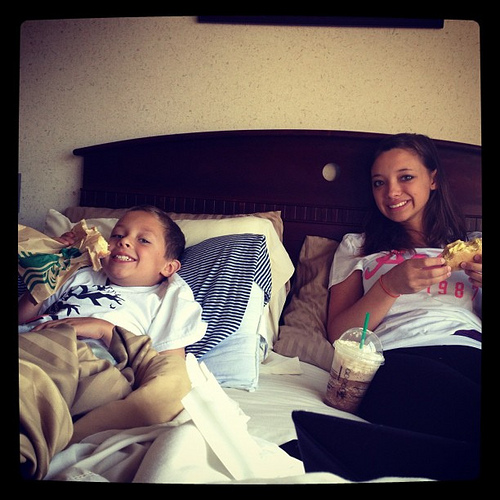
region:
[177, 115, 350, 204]
rounded brown colored headboard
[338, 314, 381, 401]
starbucks drink with whip cream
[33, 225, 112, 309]
a brown and green bag for starbucks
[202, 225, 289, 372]
blue and white striped pillow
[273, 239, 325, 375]
brown striped pillow case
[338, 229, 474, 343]
white shirt with pink lettering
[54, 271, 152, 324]
white and black t shirt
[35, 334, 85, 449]
gold colored bed spread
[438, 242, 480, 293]
a sandwhich in girls hand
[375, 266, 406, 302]
red hair band on gir'l's wrist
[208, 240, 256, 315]
a pillow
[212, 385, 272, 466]
white sheets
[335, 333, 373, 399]
a starbucks drink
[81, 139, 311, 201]
a headboard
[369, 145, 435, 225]
a women smiling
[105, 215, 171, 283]
a boy in bed smiling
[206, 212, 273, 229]
pillows on the bed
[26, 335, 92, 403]
a brown comforter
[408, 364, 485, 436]
women is wearing black pants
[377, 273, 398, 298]
a hair tie on wrisk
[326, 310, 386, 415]
Coffee drink on a bed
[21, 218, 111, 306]
Starbucks bag in a boy's hand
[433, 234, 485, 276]
Sandwich in a woman's hand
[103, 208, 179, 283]
Boy's face smiling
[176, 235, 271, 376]
Black and white sheet on a pillow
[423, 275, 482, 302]
1987 on a woman's shirt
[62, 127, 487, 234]
Head board behind a bed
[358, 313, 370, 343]
Green straw in a drink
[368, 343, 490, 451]
Woman wearing black pants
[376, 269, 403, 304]
Orange band on a girl's wrist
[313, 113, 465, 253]
the woman is smiling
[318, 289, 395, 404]
a cup of coffee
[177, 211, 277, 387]
a striped pillow case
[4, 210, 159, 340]
the boy is holding a paper bag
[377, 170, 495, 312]
the woman is holding a sandwich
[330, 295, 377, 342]
the straw is green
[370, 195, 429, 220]
the teeth are white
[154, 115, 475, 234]
the head board is brown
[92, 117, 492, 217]
the head board is made if wood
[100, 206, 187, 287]
Young boy with a smile on his face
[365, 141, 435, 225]
Teenage girl with smile on her face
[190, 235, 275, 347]
Blue and white striped pillowcase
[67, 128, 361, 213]
Dark brown headboard of bed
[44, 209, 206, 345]
Young boy wearing white shirt with black print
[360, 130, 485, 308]
Young lady holding a sandwich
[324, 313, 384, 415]
Brown and white dessert drink with green straw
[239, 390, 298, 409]
Wrinkled white bed sheet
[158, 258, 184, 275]
Left ear of young boy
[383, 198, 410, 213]
Mouth of a young lady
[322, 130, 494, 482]
young girl laying in bed eating food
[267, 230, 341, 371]
bed pillow with brown pillowcase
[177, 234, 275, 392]
bed pillow with blue and white pillowcase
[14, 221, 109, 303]
Starbuck's bag with pastry inside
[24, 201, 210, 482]
young boy eating food while in bed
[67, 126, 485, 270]
wooden headboard to bed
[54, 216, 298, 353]
bed pillow with cream-colored pillowcase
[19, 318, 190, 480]
brown bed covering over boy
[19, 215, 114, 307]
bag held by human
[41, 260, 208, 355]
shirt worn by human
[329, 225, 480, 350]
shirt worn by human